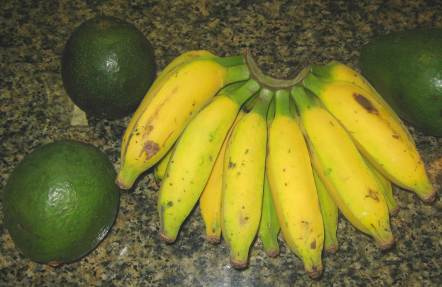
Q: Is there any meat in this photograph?
A: No, there is no meat.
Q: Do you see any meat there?
A: No, there is no meat.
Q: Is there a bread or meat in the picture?
A: No, there are no meat or breads.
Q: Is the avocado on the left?
A: Yes, the avocado is on the left of the image.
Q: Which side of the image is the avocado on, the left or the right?
A: The avocado is on the left of the image.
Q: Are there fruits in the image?
A: Yes, there is a fruit.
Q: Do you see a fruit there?
A: Yes, there is a fruit.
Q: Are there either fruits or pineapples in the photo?
A: Yes, there is a fruit.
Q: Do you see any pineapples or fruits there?
A: Yes, there is a fruit.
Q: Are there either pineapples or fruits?
A: Yes, there is a fruit.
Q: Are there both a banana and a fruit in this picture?
A: Yes, there are both a fruit and a banana.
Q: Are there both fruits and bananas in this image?
A: Yes, there are both a fruit and a banana.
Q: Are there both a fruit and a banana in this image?
A: Yes, there are both a fruit and a banana.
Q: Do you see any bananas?
A: Yes, there is a banana.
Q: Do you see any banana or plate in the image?
A: Yes, there is a banana.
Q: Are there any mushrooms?
A: No, there are no mushrooms.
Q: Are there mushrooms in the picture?
A: No, there are no mushrooms.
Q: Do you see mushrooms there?
A: No, there are no mushrooms.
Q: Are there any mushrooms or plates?
A: No, there are no mushrooms or plates.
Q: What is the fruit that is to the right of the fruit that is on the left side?
A: The fruit is a banana.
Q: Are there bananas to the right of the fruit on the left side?
A: Yes, there is a banana to the right of the fruit.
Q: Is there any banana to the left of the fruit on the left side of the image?
A: No, the banana is to the right of the fruit.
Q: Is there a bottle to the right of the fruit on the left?
A: No, there is a banana to the right of the fruit.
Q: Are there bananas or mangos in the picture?
A: Yes, there is a banana.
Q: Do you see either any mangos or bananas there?
A: Yes, there is a banana.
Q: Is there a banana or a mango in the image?
A: Yes, there is a banana.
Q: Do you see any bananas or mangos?
A: Yes, there is a banana.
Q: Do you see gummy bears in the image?
A: No, there are no gummy bears.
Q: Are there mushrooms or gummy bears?
A: No, there are no gummy bears or mushrooms.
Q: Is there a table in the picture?
A: Yes, there is a table.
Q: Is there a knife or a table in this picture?
A: Yes, there is a table.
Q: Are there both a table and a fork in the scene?
A: No, there is a table but no forks.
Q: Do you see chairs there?
A: No, there are no chairs.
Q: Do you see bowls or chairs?
A: No, there are no chairs or bowls.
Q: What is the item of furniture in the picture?
A: The piece of furniture is a table.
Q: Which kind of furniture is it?
A: The piece of furniture is a table.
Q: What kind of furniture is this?
A: This is a table.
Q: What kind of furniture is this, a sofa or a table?
A: This is a table.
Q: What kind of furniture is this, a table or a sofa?
A: This is a table.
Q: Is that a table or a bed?
A: That is a table.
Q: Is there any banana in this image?
A: Yes, there are bananas.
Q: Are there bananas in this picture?
A: Yes, there are bananas.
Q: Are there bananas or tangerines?
A: Yes, there are bananas.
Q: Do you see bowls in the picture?
A: No, there are no bowls.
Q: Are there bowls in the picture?
A: No, there are no bowls.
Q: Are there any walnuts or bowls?
A: No, there are no bowls or walnuts.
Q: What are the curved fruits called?
A: The fruits are bananas.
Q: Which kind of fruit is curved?
A: The fruit is bananas.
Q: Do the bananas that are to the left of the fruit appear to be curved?
A: Yes, the bananas are curved.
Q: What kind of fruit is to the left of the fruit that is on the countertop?
A: The fruits are bananas.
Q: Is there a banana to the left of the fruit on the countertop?
A: Yes, there are bananas to the left of the fruit.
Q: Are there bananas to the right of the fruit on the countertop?
A: No, the bananas are to the left of the fruit.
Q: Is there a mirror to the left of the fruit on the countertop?
A: No, there are bananas to the left of the fruit.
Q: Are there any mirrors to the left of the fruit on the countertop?
A: No, there are bananas to the left of the fruit.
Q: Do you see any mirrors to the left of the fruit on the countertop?
A: No, there are bananas to the left of the fruit.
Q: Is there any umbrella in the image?
A: No, there are no umbrellas.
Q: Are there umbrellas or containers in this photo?
A: No, there are no umbrellas or containers.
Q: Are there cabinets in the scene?
A: No, there are no cabinets.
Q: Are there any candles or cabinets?
A: No, there are no cabinets or candles.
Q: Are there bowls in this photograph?
A: No, there are no bowls.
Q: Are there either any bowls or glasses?
A: No, there are no bowls or glasses.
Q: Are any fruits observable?
A: Yes, there is a fruit.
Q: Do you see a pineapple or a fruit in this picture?
A: Yes, there is a fruit.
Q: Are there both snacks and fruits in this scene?
A: No, there is a fruit but no snacks.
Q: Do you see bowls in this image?
A: No, there are no bowls.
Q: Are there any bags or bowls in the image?
A: No, there are no bowls or bags.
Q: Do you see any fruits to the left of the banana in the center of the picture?
A: Yes, there is a fruit to the left of the banana.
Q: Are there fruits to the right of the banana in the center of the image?
A: No, the fruit is to the left of the banana.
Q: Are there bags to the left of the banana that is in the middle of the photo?
A: No, there is a fruit to the left of the banana.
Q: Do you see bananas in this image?
A: Yes, there is a banana.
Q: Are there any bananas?
A: Yes, there is a banana.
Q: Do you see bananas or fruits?
A: Yes, there is a banana.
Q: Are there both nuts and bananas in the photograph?
A: No, there is a banana but no nuts.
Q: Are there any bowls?
A: No, there are no bowls.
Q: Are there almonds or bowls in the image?
A: No, there are no bowls or almonds.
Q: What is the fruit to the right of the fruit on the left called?
A: The fruit is a banana.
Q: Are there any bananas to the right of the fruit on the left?
A: Yes, there is a banana to the right of the fruit.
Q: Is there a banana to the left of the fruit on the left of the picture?
A: No, the banana is to the right of the fruit.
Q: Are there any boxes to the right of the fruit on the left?
A: No, there is a banana to the right of the fruit.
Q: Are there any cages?
A: No, there are no cages.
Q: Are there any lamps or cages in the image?
A: No, there are no cages or lamps.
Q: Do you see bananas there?
A: Yes, there is a banana.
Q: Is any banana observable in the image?
A: Yes, there is a banana.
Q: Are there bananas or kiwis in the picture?
A: Yes, there is a banana.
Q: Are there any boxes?
A: No, there are no boxes.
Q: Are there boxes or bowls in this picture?
A: No, there are no boxes or bowls.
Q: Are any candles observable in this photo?
A: No, there are no candles.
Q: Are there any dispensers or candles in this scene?
A: No, there are no candles or dispensers.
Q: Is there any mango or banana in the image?
A: Yes, there is a banana.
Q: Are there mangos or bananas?
A: Yes, there is a banana.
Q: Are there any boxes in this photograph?
A: No, there are no boxes.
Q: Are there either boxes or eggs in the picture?
A: No, there are no boxes or eggs.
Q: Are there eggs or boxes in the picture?
A: No, there are no boxes or eggs.